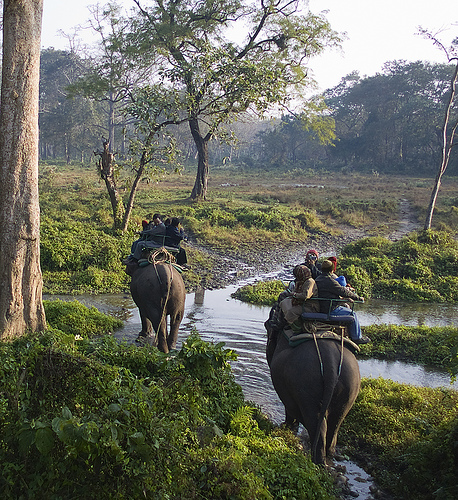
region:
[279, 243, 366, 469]
people riding an elephant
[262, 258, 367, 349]
Several people atop an elephant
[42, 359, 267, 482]
Lots of green foliage next to the water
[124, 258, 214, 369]
An elephant walking in water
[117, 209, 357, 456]
Two elephants carrying people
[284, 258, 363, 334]
The people are in a basket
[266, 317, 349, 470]
A large elephants rear end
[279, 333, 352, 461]
The elephant is very wide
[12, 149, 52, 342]
A tall tree with white bark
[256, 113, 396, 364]
An elephant walking through a wet and soggy area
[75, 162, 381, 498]
two elephants that are walk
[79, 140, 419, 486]
two elephants carrying people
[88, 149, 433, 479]
two elephants carrying people on their backs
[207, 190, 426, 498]
an elephant walking in the water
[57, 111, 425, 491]
elephant walking in water with people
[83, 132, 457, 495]
two large elephants walking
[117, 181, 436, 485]
two large elephants walking in the water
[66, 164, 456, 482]
a stream of water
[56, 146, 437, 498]
an area of grass trees and water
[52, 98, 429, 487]
large elephants walking togehter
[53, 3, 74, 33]
white clouds in light blue sky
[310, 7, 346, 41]
white clouds in light blue sky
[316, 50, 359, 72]
white clouds in light blue sky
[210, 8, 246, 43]
white clouds in light blue sky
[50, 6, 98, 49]
white clouds in light blue sky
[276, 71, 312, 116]
white clouds in light blue sky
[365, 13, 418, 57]
white clouds in light blue sky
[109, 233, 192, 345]
gray elephants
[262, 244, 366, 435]
gray elephants with people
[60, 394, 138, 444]
green bushes on shore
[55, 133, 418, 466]
People are going on a safari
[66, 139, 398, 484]
People are riding some elephants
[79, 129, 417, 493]
Elephants are walking through some water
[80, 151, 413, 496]
Elephants have people on their backs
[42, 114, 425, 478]
Elephants are being used for travel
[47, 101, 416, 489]
Elephants are moving through the jungle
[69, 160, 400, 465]
People are enjoying the ride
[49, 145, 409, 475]
Elephants are taking people home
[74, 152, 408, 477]
Elephants are doing some work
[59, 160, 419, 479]
A male and a female elephant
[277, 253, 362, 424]
people riding gray elephants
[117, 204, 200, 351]
people riding gray elephants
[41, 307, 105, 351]
short green grass near river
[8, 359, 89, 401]
short green grass near river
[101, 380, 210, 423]
short green grass near river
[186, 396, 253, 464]
short green grass near river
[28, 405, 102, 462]
short green grass near river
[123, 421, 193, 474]
short green grass near river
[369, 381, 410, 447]
short green grass near river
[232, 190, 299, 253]
short green grass near river